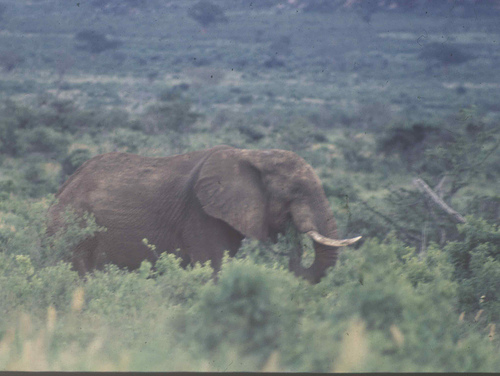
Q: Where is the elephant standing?
A: In the bush.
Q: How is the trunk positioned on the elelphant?
A: In the mouth.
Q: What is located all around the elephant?
A: Green brush.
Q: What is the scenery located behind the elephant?
A: Level green plain.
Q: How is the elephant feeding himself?
A: Putting food in its mouth with trunk.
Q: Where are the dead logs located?
A: In front of the elephant.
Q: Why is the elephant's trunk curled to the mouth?
A: Feeding itself.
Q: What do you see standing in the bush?
A: An elephant.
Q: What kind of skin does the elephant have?
A: Wrinkly skin.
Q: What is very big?
A: The elephant.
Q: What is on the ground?
A: A pile of fallen trees.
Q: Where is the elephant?
A: In the wild.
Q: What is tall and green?
A: The bushes.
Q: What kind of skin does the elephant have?
A: Grey skin.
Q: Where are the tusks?
A: Beside the trunk.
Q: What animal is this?
A: An elephant.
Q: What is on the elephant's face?
A: Tusks.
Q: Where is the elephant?
A: In the grass.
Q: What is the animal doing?
A: Eating.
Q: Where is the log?
A: Near the animal.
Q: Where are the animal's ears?
A: On its head.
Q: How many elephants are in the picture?
A: One.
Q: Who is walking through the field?
A: An elephant.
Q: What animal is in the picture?
A: An elephant.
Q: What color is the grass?
A: Green.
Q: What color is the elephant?
A: Gray.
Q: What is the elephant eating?
A: Grass.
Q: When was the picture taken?
A: During the day.